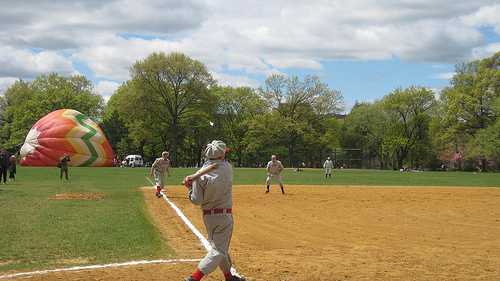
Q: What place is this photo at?
A: It is at the field.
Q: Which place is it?
A: It is a field.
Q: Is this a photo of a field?
A: Yes, it is showing a field.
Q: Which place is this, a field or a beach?
A: It is a field.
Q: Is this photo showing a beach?
A: No, the picture is showing a field.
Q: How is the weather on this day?
A: It is clear.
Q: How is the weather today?
A: It is clear.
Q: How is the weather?
A: It is clear.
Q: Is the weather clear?
A: Yes, it is clear.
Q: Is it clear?
A: Yes, it is clear.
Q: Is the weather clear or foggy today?
A: It is clear.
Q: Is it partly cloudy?
A: No, it is clear.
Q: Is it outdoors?
A: Yes, it is outdoors.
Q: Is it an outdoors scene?
A: Yes, it is outdoors.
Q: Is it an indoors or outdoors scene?
A: It is outdoors.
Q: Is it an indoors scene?
A: No, it is outdoors.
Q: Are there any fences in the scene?
A: No, there are no fences.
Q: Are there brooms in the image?
A: No, there are no brooms.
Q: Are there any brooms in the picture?
A: No, there are no brooms.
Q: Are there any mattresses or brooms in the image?
A: No, there are no brooms or mattresses.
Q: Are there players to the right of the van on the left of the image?
A: Yes, there is a player to the right of the van.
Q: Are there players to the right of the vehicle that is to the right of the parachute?
A: Yes, there is a player to the right of the van.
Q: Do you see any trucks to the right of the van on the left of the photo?
A: No, there is a player to the right of the van.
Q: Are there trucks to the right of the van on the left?
A: No, there is a player to the right of the van.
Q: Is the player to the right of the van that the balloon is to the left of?
A: Yes, the player is to the right of the van.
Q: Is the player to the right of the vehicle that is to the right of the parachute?
A: Yes, the player is to the right of the van.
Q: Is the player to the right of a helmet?
A: No, the player is to the right of the van.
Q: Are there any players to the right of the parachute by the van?
A: Yes, there is a player to the right of the parachute.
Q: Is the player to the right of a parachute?
A: Yes, the player is to the right of a parachute.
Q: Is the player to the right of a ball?
A: No, the player is to the right of a parachute.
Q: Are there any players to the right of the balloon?
A: Yes, there is a player to the right of the balloon.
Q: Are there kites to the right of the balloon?
A: No, there is a player to the right of the balloon.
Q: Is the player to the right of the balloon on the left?
A: Yes, the player is to the right of the balloon.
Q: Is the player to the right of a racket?
A: No, the player is to the right of the balloon.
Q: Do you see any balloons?
A: Yes, there is a balloon.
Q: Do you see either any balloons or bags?
A: Yes, there is a balloon.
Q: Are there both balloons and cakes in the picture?
A: No, there is a balloon but no cakes.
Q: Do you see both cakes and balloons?
A: No, there is a balloon but no cakes.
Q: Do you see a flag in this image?
A: No, there are no flags.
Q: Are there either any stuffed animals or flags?
A: No, there are no flags or stuffed animals.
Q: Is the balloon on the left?
A: Yes, the balloon is on the left of the image.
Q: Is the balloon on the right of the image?
A: No, the balloon is on the left of the image.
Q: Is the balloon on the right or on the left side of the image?
A: The balloon is on the left of the image.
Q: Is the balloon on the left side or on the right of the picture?
A: The balloon is on the left of the image.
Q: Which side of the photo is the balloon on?
A: The balloon is on the left of the image.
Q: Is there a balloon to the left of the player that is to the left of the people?
A: Yes, there is a balloon to the left of the player.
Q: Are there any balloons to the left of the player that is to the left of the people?
A: Yes, there is a balloon to the left of the player.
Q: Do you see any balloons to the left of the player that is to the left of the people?
A: Yes, there is a balloon to the left of the player.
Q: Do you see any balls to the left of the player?
A: No, there is a balloon to the left of the player.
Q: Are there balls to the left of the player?
A: No, there is a balloon to the left of the player.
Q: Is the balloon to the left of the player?
A: Yes, the balloon is to the left of the player.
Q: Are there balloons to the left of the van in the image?
A: Yes, there is a balloon to the left of the van.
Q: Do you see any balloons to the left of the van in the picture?
A: Yes, there is a balloon to the left of the van.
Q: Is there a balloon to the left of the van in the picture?
A: Yes, there is a balloon to the left of the van.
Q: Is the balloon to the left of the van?
A: Yes, the balloon is to the left of the van.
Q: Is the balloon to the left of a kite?
A: No, the balloon is to the left of the van.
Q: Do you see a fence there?
A: No, there are no fences.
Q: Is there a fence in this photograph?
A: No, there are no fences.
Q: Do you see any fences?
A: No, there are no fences.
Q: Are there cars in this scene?
A: No, there are no cars.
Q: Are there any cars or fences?
A: No, there are no cars or fences.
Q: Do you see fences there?
A: No, there are no fences.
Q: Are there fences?
A: No, there are no fences.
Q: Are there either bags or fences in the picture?
A: No, there are no fences or bags.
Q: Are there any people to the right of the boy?
A: Yes, there are people to the right of the boy.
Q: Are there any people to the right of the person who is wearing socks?
A: Yes, there are people to the right of the boy.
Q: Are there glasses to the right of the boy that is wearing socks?
A: No, there are people to the right of the boy.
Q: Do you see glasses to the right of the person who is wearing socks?
A: No, there are people to the right of the boy.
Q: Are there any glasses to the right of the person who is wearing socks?
A: No, there are people to the right of the boy.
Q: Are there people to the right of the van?
A: Yes, there are people to the right of the van.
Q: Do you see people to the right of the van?
A: Yes, there are people to the right of the van.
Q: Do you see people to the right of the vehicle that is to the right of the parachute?
A: Yes, there are people to the right of the van.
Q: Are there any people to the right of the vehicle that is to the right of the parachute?
A: Yes, there are people to the right of the van.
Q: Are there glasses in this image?
A: No, there are no glasses.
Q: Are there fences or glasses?
A: No, there are no glasses or fences.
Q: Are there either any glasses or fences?
A: No, there are no glasses or fences.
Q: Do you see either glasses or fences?
A: No, there are no glasses or fences.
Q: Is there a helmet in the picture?
A: No, there are no helmets.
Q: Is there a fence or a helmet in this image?
A: No, there are no helmets or fences.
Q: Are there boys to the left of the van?
A: No, the boy is to the right of the van.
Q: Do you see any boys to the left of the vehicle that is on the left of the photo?
A: No, the boy is to the right of the van.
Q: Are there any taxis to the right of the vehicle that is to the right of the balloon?
A: No, there is a boy to the right of the van.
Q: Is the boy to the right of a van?
A: Yes, the boy is to the right of a van.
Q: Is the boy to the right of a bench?
A: No, the boy is to the right of a van.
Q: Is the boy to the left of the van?
A: No, the boy is to the right of the van.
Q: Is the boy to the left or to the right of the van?
A: The boy is to the right of the van.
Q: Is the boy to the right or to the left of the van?
A: The boy is to the right of the van.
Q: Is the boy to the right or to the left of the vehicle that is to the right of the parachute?
A: The boy is to the right of the van.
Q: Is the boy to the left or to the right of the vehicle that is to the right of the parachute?
A: The boy is to the right of the van.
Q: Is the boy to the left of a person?
A: Yes, the boy is to the left of a person.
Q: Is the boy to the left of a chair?
A: No, the boy is to the left of a person.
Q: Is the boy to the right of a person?
A: No, the boy is to the left of a person.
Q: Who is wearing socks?
A: The boy is wearing socks.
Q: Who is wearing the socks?
A: The boy is wearing socks.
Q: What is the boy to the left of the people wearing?
A: The boy is wearing socks.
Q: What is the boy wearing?
A: The boy is wearing socks.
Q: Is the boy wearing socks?
A: Yes, the boy is wearing socks.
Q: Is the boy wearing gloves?
A: No, the boy is wearing socks.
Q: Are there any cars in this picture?
A: No, there are no cars.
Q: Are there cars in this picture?
A: No, there are no cars.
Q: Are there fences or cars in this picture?
A: No, there are no cars or fences.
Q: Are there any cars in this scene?
A: No, there are no cars.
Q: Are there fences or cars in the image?
A: No, there are no cars or fences.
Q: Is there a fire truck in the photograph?
A: No, there are no fire trucks.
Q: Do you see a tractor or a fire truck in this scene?
A: No, there are no fire trucks or tractors.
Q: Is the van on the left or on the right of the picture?
A: The van is on the left of the image.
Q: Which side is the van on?
A: The van is on the left of the image.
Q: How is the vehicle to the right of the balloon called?
A: The vehicle is a van.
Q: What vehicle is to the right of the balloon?
A: The vehicle is a van.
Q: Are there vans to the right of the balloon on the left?
A: Yes, there is a van to the right of the balloon.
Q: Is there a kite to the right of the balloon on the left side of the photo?
A: No, there is a van to the right of the balloon.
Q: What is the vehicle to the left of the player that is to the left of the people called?
A: The vehicle is a van.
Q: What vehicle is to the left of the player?
A: The vehicle is a van.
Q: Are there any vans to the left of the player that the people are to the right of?
A: Yes, there is a van to the left of the player.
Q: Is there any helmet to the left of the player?
A: No, there is a van to the left of the player.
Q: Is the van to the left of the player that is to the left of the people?
A: Yes, the van is to the left of the player.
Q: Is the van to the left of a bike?
A: No, the van is to the left of the player.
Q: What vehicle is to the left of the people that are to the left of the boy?
A: The vehicle is a van.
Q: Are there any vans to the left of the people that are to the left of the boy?
A: Yes, there is a van to the left of the people.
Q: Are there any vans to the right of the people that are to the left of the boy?
A: No, the van is to the left of the people.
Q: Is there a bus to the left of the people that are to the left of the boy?
A: No, there is a van to the left of the people.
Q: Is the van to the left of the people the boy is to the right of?
A: Yes, the van is to the left of the people.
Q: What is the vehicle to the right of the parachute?
A: The vehicle is a van.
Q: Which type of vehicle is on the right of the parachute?
A: The vehicle is a van.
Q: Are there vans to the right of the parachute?
A: Yes, there is a van to the right of the parachute.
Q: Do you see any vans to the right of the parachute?
A: Yes, there is a van to the right of the parachute.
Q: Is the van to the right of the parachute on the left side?
A: Yes, the van is to the right of the parachute.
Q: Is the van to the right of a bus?
A: No, the van is to the right of the parachute.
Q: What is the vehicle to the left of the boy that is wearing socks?
A: The vehicle is a van.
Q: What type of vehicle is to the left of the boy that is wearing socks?
A: The vehicle is a van.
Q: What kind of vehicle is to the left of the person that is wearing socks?
A: The vehicle is a van.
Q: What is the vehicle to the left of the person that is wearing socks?
A: The vehicle is a van.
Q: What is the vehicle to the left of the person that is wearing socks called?
A: The vehicle is a van.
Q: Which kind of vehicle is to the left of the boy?
A: The vehicle is a van.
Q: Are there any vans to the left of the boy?
A: Yes, there is a van to the left of the boy.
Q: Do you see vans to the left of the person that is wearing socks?
A: Yes, there is a van to the left of the boy.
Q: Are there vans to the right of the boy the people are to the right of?
A: No, the van is to the left of the boy.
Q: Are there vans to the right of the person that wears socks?
A: No, the van is to the left of the boy.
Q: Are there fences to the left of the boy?
A: No, there is a van to the left of the boy.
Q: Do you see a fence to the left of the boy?
A: No, there is a van to the left of the boy.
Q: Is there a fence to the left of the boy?
A: No, there is a van to the left of the boy.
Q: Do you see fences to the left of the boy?
A: No, there is a van to the left of the boy.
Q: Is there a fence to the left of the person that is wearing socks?
A: No, there is a van to the left of the boy.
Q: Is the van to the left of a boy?
A: Yes, the van is to the left of a boy.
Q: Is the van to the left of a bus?
A: No, the van is to the left of a boy.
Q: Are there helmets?
A: No, there are no helmets.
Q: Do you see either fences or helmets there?
A: No, there are no helmets or fences.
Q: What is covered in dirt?
A: The field is covered in dirt.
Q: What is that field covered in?
A: The field is covered in dirt.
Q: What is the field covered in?
A: The field is covered in dirt.